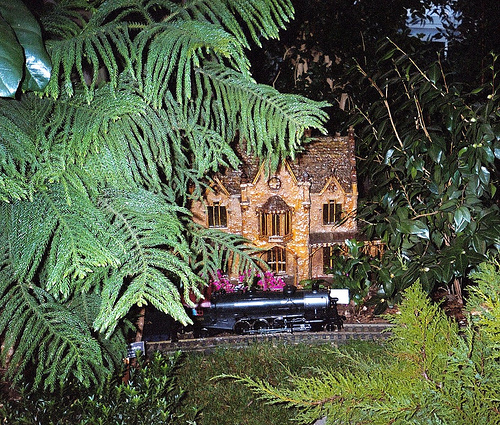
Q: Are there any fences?
A: No, there are no fences.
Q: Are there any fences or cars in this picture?
A: No, there are no fences or cars.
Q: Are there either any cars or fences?
A: No, there are no fences or cars.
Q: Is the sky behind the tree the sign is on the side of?
A: Yes, the sky is behind the tree.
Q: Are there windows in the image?
A: Yes, there is a window.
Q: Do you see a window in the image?
A: Yes, there is a window.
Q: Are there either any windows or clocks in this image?
A: Yes, there is a window.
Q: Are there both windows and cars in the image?
A: No, there is a window but no cars.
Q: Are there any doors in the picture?
A: No, there are no doors.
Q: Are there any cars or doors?
A: No, there are no doors or cars.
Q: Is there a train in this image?
A: Yes, there is a train.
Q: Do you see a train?
A: Yes, there is a train.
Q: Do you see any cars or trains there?
A: Yes, there is a train.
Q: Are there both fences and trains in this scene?
A: No, there is a train but no fences.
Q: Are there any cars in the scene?
A: No, there are no cars.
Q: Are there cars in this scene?
A: No, there are no cars.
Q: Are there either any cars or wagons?
A: No, there are no cars or wagons.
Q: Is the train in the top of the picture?
A: No, the train is in the bottom of the image.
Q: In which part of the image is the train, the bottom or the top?
A: The train is in the bottom of the image.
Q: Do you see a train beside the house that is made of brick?
A: Yes, there is a train beside the house.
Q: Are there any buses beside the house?
A: No, there is a train beside the house.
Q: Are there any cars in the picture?
A: No, there are no cars.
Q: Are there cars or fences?
A: No, there are no cars or fences.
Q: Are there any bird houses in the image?
A: No, there are no bird houses.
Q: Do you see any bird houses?
A: No, there are no bird houses.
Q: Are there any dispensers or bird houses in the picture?
A: No, there are no bird houses or dispensers.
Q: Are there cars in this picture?
A: No, there are no cars.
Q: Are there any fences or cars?
A: No, there are no cars or fences.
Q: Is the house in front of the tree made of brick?
A: Yes, the house is made of brick.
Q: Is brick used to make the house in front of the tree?
A: Yes, the house is made of brick.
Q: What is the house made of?
A: The house is made of brick.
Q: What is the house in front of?
A: The house is in front of the tree.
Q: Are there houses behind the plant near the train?
A: Yes, there is a house behind the plant.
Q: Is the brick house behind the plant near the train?
A: Yes, the house is behind the plant.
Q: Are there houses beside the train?
A: Yes, there is a house beside the train.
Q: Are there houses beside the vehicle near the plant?
A: Yes, there is a house beside the train.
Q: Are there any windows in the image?
A: Yes, there is a window.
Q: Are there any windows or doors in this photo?
A: Yes, there is a window.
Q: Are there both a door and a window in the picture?
A: No, there is a window but no doors.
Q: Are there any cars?
A: No, there are no cars.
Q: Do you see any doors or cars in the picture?
A: No, there are no cars or doors.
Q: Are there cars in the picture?
A: No, there are no cars.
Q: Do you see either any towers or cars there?
A: No, there are no cars or towers.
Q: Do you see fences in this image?
A: No, there are no fences.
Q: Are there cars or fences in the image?
A: No, there are no fences or cars.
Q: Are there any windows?
A: Yes, there is a window.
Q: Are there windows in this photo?
A: Yes, there is a window.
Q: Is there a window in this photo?
A: Yes, there is a window.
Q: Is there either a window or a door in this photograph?
A: Yes, there is a window.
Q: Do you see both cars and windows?
A: No, there is a window but no cars.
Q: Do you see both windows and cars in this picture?
A: No, there is a window but no cars.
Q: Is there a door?
A: No, there are no doors.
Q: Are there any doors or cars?
A: No, there are no doors or cars.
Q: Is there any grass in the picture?
A: Yes, there is grass.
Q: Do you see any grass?
A: Yes, there is grass.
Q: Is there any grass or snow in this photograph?
A: Yes, there is grass.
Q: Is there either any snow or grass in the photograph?
A: Yes, there is grass.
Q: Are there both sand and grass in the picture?
A: No, there is grass but no sand.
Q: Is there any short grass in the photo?
A: Yes, there is short grass.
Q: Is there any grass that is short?
A: Yes, there is grass that is short.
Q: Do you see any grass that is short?
A: Yes, there is grass that is short.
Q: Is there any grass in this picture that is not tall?
A: Yes, there is short grass.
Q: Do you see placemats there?
A: No, there are no placemats.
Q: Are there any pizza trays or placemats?
A: No, there are no placemats or pizza trays.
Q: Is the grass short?
A: Yes, the grass is short.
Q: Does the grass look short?
A: Yes, the grass is short.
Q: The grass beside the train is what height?
A: The grass is short.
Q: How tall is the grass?
A: The grass is short.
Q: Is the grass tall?
A: No, the grass is short.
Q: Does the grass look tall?
A: No, the grass is short.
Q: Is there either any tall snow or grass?
A: No, there is grass but it is short.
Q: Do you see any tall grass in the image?
A: No, there is grass but it is short.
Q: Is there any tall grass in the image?
A: No, there is grass but it is short.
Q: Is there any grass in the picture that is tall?
A: No, there is grass but it is short.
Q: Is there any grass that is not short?
A: No, there is grass but it is short.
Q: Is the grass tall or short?
A: The grass is short.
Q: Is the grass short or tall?
A: The grass is short.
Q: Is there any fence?
A: No, there are no fences.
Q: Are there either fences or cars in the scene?
A: No, there are no fences or cars.